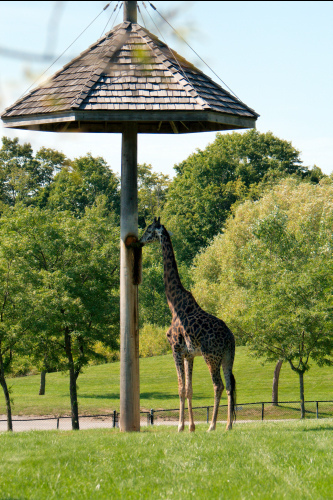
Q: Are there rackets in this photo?
A: No, there are no rackets.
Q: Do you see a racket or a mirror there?
A: No, there are no rackets or mirrors.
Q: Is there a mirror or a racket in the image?
A: No, there are no rackets or mirrors.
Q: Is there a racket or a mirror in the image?
A: No, there are no rackets or mirrors.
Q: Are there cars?
A: No, there are no cars.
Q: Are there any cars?
A: No, there are no cars.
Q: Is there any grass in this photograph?
A: Yes, there is grass.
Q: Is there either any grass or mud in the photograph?
A: Yes, there is grass.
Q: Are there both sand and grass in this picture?
A: No, there is grass but no sand.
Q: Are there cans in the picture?
A: No, there are no cans.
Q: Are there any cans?
A: No, there are no cans.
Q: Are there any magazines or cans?
A: No, there are no cans or magazines.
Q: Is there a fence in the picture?
A: Yes, there is a fence.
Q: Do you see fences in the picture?
A: Yes, there is a fence.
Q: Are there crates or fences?
A: Yes, there is a fence.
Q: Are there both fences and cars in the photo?
A: No, there is a fence but no cars.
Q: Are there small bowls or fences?
A: Yes, there is a small fence.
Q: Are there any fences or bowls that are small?
A: Yes, the fence is small.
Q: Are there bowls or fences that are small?
A: Yes, the fence is small.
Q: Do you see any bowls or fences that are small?
A: Yes, the fence is small.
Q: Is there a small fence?
A: Yes, there is a small fence.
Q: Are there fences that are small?
A: Yes, there is a fence that is small.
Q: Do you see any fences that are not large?
A: Yes, there is a small fence.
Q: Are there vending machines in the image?
A: No, there are no vending machines.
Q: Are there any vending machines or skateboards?
A: No, there are no vending machines or skateboards.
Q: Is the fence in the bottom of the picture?
A: Yes, the fence is in the bottom of the image.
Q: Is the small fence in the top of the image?
A: No, the fence is in the bottom of the image.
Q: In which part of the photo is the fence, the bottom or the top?
A: The fence is in the bottom of the image.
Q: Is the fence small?
A: Yes, the fence is small.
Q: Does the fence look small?
A: Yes, the fence is small.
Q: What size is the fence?
A: The fence is small.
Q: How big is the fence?
A: The fence is small.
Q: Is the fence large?
A: No, the fence is small.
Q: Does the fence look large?
A: No, the fence is small.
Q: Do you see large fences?
A: No, there is a fence but it is small.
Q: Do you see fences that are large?
A: No, there is a fence but it is small.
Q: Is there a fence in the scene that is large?
A: No, there is a fence but it is small.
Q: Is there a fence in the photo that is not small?
A: No, there is a fence but it is small.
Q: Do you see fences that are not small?
A: No, there is a fence but it is small.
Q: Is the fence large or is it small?
A: The fence is small.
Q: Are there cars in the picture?
A: No, there are no cars.